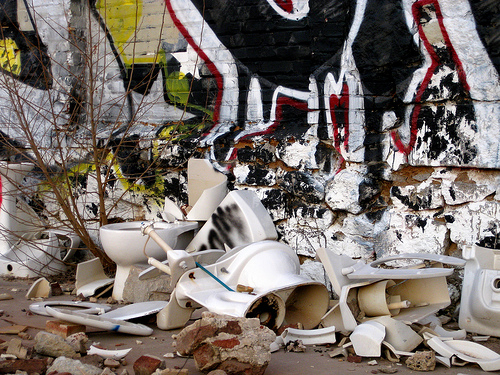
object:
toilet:
[178, 239, 330, 321]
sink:
[458, 262, 498, 327]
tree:
[1, 72, 113, 267]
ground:
[0, 284, 103, 334]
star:
[170, 39, 205, 81]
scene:
[0, 0, 497, 368]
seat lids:
[44, 308, 155, 336]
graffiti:
[0, 0, 214, 92]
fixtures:
[0, 158, 499, 373]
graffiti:
[197, 201, 250, 251]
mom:
[198, 204, 247, 254]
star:
[114, 60, 195, 147]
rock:
[63, 329, 92, 352]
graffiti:
[363, 127, 468, 158]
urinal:
[458, 244, 500, 342]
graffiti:
[334, 183, 478, 230]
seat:
[96, 215, 181, 254]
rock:
[32, 332, 79, 359]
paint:
[167, 182, 182, 196]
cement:
[275, 352, 283, 361]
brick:
[130, 354, 165, 375]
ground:
[104, 342, 191, 371]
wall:
[4, 7, 484, 180]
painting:
[14, 9, 497, 234]